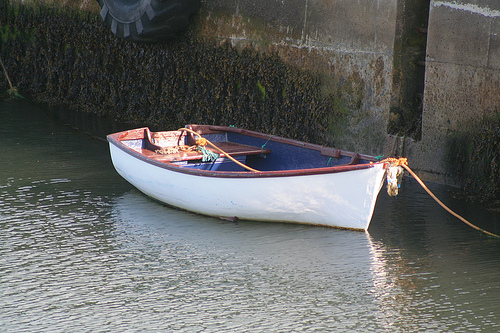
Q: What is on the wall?
A: Tire.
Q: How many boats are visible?
A: 1.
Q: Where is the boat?
A: Water.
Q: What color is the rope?
A: Orange.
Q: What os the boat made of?
A: Wood.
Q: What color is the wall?
A: Grey.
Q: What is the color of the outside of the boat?
A: White.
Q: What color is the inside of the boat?
A: Blue.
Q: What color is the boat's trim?
A: Red.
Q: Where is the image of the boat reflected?
A: Water.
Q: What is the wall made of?
A: Stone.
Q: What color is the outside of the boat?
A: White.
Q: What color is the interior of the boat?
A: Blue.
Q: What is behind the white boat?
A: A wall.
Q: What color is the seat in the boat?
A: Brown.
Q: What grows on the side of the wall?
A: Green moss.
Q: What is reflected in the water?
A: The boat.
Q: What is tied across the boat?
A: A rope.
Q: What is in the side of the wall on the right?
A: A drain.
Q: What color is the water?
A: Grey.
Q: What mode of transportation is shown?
A: Boat.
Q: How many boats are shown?
A: 1.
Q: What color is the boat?
A: White.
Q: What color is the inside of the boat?
A: Blue.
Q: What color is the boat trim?
A: Red brown.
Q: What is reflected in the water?
A: Boat.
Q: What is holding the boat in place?
A: Rope.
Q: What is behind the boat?
A: Wall.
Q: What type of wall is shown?
A: Concrete.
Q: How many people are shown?
A: 0.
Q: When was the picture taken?
A: Daytime.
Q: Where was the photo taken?
A: On the water.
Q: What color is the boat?
A: White.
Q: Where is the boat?
A: In the water.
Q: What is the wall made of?
A: Cement.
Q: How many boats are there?
A: One.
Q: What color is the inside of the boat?
A: Blue.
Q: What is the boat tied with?
A: A rope.